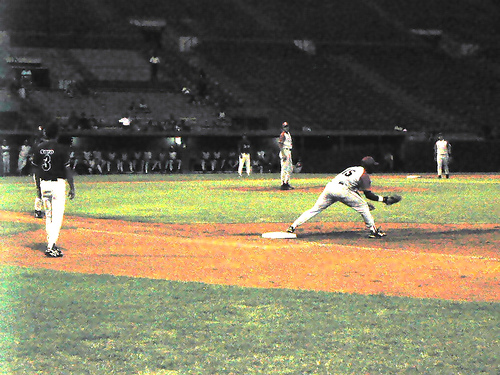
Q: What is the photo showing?
A: It is showing a stadium.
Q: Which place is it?
A: It is a stadium.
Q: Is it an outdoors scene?
A: Yes, it is outdoors.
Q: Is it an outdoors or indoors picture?
A: It is outdoors.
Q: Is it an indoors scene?
A: No, it is outdoors.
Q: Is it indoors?
A: No, it is outdoors.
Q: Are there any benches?
A: Yes, there is a bench.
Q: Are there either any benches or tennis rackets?
A: Yes, there is a bench.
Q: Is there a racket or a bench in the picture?
A: Yes, there is a bench.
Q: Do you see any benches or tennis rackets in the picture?
A: Yes, there is a bench.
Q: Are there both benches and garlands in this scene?
A: No, there is a bench but no garlands.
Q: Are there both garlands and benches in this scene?
A: No, there is a bench but no garlands.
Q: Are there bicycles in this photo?
A: No, there are no bicycles.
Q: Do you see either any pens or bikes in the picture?
A: No, there are no bikes or pens.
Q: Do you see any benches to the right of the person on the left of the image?
A: Yes, there is a bench to the right of the person.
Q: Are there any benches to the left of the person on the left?
A: No, the bench is to the right of the person.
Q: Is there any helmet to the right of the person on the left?
A: No, there is a bench to the right of the person.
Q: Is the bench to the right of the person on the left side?
A: Yes, the bench is to the right of the person.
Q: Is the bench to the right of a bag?
A: No, the bench is to the right of the person.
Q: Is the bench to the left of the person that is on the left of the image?
A: No, the bench is to the right of the person.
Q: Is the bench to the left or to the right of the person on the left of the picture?
A: The bench is to the right of the person.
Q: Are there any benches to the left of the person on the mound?
A: Yes, there is a bench to the left of the person.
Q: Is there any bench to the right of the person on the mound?
A: No, the bench is to the left of the person.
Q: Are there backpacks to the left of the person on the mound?
A: No, there is a bench to the left of the person.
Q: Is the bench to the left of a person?
A: Yes, the bench is to the left of a person.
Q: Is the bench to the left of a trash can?
A: No, the bench is to the left of a person.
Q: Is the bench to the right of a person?
A: No, the bench is to the left of a person.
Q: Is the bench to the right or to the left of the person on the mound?
A: The bench is to the left of the person.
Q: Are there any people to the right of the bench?
A: Yes, there is a person to the right of the bench.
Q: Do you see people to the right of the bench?
A: Yes, there is a person to the right of the bench.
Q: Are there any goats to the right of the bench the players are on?
A: No, there is a person to the right of the bench.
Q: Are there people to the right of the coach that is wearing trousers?
A: Yes, there is a person to the right of the coach.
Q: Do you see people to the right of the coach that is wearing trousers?
A: Yes, there is a person to the right of the coach.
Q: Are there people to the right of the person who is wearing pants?
A: Yes, there is a person to the right of the coach.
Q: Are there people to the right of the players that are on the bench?
A: Yes, there is a person to the right of the players.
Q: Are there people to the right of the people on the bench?
A: Yes, there is a person to the right of the players.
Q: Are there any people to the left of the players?
A: No, the person is to the right of the players.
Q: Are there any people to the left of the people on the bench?
A: No, the person is to the right of the players.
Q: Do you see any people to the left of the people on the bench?
A: No, the person is to the right of the players.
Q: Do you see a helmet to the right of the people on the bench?
A: No, there is a person to the right of the players.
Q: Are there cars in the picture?
A: No, there are no cars.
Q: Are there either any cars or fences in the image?
A: No, there are no cars or fences.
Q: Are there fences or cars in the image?
A: No, there are no cars or fences.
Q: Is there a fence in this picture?
A: No, there are no fences.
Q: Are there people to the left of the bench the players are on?
A: Yes, there is a person to the left of the bench.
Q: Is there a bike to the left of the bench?
A: No, there is a person to the left of the bench.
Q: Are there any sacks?
A: No, there are no sacks.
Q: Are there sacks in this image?
A: No, there are no sacks.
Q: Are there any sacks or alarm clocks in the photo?
A: No, there are no sacks or alarm clocks.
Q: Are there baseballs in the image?
A: Yes, there is a baseball.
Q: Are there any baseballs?
A: Yes, there is a baseball.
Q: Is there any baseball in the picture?
A: Yes, there is a baseball.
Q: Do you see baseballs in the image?
A: Yes, there is a baseball.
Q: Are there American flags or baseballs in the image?
A: Yes, there is a baseball.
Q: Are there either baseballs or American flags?
A: Yes, there is a baseball.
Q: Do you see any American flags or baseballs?
A: Yes, there is a baseball.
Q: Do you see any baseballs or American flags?
A: Yes, there is a baseball.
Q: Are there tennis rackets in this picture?
A: No, there are no tennis rackets.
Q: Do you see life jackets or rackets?
A: No, there are no rackets or life jackets.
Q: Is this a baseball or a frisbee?
A: This is a baseball.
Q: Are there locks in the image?
A: No, there are no locks.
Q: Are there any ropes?
A: No, there are no ropes.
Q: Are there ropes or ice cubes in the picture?
A: No, there are no ropes or ice cubes.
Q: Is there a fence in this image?
A: No, there are no fences.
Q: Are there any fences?
A: No, there are no fences.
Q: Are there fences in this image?
A: No, there are no fences.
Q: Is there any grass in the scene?
A: Yes, there is grass.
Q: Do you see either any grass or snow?
A: Yes, there is grass.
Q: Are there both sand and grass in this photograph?
A: No, there is grass but no sand.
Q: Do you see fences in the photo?
A: No, there are no fences.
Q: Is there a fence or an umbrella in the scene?
A: No, there are no fences or umbrellas.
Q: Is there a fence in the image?
A: No, there are no fences.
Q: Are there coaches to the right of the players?
A: Yes, there is a coach to the right of the players.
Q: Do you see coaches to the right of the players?
A: Yes, there is a coach to the right of the players.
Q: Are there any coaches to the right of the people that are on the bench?
A: Yes, there is a coach to the right of the players.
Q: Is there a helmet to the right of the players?
A: No, there is a coach to the right of the players.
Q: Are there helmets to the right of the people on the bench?
A: No, there is a coach to the right of the players.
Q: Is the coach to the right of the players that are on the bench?
A: Yes, the coach is to the right of the players.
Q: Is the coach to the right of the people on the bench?
A: Yes, the coach is to the right of the players.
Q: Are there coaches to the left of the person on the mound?
A: Yes, there is a coach to the left of the person.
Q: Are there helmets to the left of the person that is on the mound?
A: No, there is a coach to the left of the person.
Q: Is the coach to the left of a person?
A: Yes, the coach is to the left of a person.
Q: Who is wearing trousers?
A: The coach is wearing trousers.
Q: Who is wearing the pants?
A: The coach is wearing trousers.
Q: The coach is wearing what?
A: The coach is wearing trousers.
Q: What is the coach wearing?
A: The coach is wearing trousers.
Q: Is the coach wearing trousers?
A: Yes, the coach is wearing trousers.